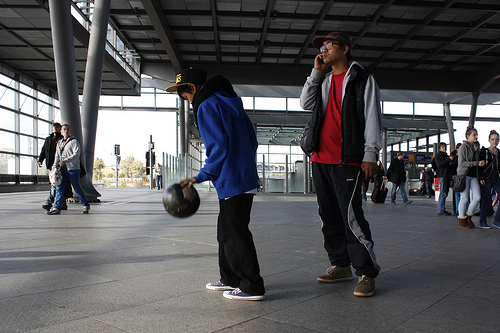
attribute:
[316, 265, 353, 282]
shoe — athletic, brown, white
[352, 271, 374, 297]
shoe — brown, white, athletic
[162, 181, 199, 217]
ball — brown, bouncing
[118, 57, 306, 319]
jacket — blue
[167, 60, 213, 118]
hat — black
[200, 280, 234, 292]
shoe — grey, white, athletic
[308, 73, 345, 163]
t-shirt — red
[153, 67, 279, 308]
boy — young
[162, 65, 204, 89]
baseball hat — black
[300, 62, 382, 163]
sweatshirt — grey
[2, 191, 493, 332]
floor — grey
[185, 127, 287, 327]
pants — black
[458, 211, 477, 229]
boots — brown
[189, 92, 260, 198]
jacket — black, grey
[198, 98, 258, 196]
jacket — blue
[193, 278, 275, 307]
shoes — grey, white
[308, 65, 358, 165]
t-shirt — red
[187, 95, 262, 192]
jacket — blue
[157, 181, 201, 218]
basketball — black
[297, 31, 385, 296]
boy — older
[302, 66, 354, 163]
shirt — red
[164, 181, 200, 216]
ball — blackish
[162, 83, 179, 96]
bill — yellow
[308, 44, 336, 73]
phone — cell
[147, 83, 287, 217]
jacket — dark blue